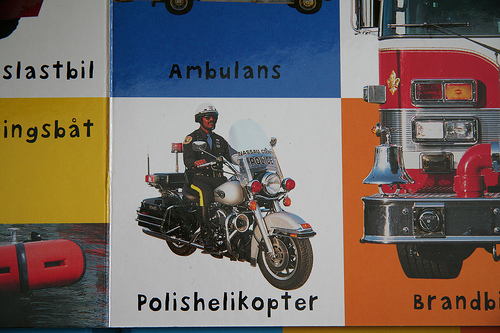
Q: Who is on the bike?
A: The person.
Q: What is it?
A: Picture.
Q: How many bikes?
A: 1.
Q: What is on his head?
A: Helmet.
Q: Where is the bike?
A: Next to the letters.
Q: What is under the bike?
A: Letters.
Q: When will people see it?
A: Soon.